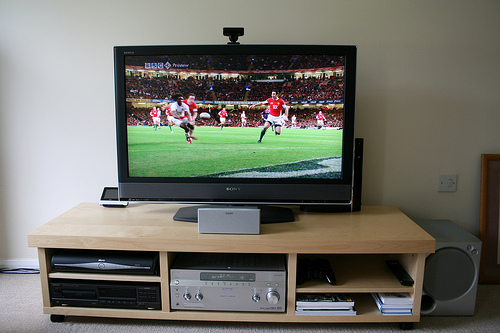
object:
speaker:
[196, 205, 263, 235]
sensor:
[220, 26, 243, 45]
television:
[113, 40, 361, 222]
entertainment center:
[26, 201, 432, 328]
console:
[40, 274, 168, 319]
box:
[44, 252, 164, 277]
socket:
[438, 166, 455, 194]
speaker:
[422, 223, 483, 318]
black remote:
[387, 259, 414, 288]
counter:
[28, 202, 435, 252]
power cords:
[0, 265, 43, 275]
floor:
[0, 272, 35, 331]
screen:
[126, 52, 341, 177]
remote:
[323, 261, 341, 284]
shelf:
[23, 198, 449, 327]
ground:
[302, 118, 337, 152]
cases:
[294, 295, 356, 318]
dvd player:
[52, 253, 153, 275]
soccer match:
[123, 55, 348, 176]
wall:
[0, 0, 499, 275]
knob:
[267, 291, 280, 301]